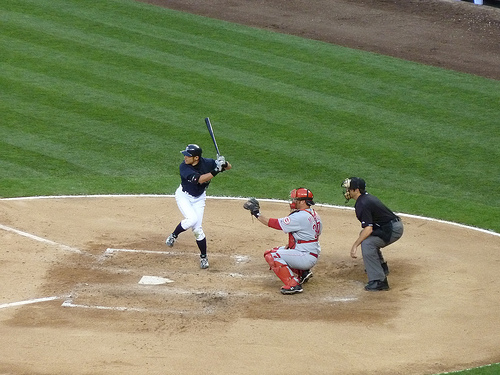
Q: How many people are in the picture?
A: 3.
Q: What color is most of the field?
A: Green.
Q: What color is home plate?
A: White.